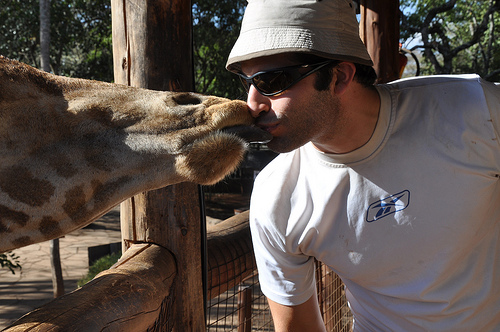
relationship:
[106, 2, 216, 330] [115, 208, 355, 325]
post to fence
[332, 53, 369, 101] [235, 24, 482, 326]
ear of man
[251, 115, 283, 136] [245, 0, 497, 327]
lips of man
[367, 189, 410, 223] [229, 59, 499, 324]
logo on shirt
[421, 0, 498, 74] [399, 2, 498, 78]
branch on tree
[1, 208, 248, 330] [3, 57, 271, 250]
wooden fence in front of giraffe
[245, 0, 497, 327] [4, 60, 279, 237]
man kissing giraffe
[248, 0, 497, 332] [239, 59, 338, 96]
man wearing black glasses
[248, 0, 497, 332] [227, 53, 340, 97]
man wearing sunglasses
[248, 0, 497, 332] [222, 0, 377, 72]
man wearing hat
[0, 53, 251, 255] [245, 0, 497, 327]
giraffe licking man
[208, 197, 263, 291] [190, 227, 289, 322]
metal mesh on wooden fence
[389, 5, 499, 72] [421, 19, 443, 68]
tree with branches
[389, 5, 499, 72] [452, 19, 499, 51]
tree with branches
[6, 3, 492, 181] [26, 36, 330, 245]
foliage behind head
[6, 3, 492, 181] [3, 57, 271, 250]
foliage behind giraffe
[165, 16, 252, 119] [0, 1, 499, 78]
foliage with sky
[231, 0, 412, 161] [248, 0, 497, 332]
head of a man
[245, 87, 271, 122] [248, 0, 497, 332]
nose of a man